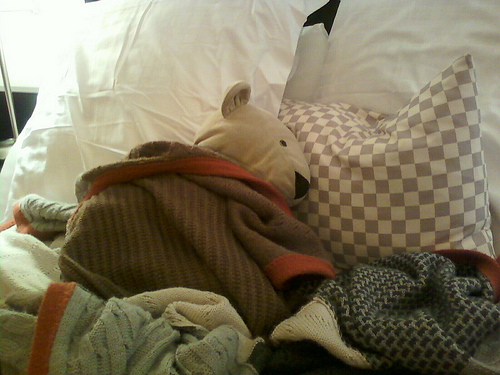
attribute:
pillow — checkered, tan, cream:
[278, 52, 497, 271]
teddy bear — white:
[191, 80, 312, 207]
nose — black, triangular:
[293, 171, 312, 201]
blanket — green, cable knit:
[0, 280, 259, 373]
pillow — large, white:
[0, 0, 330, 229]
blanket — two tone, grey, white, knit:
[271, 247, 498, 374]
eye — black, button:
[278, 138, 288, 148]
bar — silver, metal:
[1, 55, 19, 142]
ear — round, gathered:
[216, 80, 251, 117]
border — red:
[82, 155, 296, 217]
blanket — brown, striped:
[55, 140, 337, 337]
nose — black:
[291, 169, 311, 200]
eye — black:
[277, 136, 288, 150]